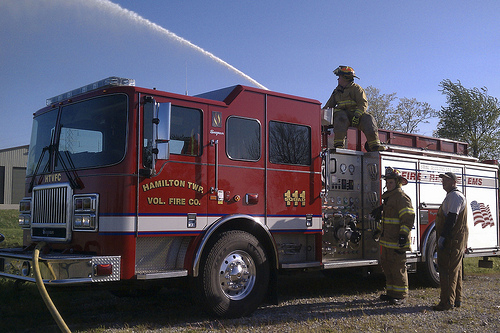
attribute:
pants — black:
[434, 210, 465, 306]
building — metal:
[0, 142, 32, 209]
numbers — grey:
[244, 172, 306, 208]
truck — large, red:
[14, 41, 494, 281]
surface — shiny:
[0, 256, 95, 281]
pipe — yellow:
[23, 252, 62, 332]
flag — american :
[469, 196, 485, 236]